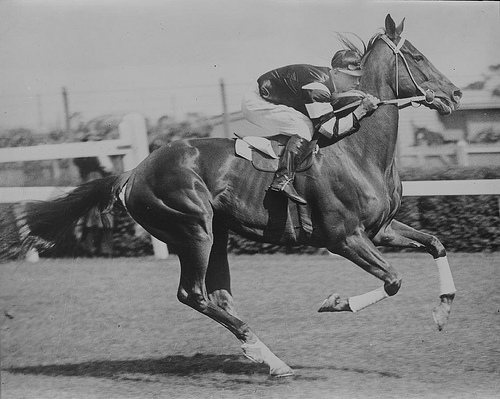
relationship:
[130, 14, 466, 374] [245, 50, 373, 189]
horse with rider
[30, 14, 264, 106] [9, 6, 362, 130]
clouds in sky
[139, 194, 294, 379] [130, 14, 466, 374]
legs of horse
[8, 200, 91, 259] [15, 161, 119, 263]
hair of tail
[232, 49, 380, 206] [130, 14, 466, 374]
man riding horse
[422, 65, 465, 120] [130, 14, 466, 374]
snout of horse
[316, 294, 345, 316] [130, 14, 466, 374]
hoof of horse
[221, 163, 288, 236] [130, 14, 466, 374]
cage on horse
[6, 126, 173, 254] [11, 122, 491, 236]
fence of enclosure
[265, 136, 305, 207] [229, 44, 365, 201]
boot of jockey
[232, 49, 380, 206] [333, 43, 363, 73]
man has cap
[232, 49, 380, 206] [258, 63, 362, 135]
man has shirt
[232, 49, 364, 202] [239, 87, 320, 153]
man has pants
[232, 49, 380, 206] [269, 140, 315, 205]
man has boots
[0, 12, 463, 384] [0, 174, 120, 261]
horse has hair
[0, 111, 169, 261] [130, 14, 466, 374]
fence behind horse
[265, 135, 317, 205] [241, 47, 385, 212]
boot of jockey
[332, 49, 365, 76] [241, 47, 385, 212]
cap on jockey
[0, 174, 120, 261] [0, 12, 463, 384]
hair of horse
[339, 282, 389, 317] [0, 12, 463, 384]
ankles on horse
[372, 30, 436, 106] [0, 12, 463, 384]
bridle on horse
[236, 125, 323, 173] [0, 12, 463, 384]
saddle on horse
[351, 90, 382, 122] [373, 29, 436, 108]
hand holding bridle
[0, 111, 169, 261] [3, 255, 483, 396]
fence by track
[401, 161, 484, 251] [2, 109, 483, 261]
shrubs behind fence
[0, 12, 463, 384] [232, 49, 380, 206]
horse with man